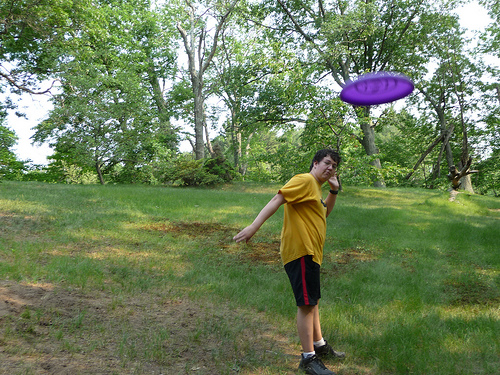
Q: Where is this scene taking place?
A: A park.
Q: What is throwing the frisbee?
A: The man.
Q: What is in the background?
A: The trees.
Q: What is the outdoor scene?
A: It was taken.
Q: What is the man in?
A: Shorts.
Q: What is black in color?
A: Shorts.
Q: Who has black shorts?
A: The man.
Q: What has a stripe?
A: Shorts.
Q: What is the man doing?
A: Playing.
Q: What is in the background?
A: Trees.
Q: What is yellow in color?
A: Shirt.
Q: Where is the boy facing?
A: To the right.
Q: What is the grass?
A: Green.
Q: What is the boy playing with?
A: Frisbee.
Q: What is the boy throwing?
A: A frisbee.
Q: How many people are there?
A: One.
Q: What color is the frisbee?
A: Purple.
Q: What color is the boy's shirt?
A: Yellow.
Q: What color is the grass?
A: Green.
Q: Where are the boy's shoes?
A: On his feet.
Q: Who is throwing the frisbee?
A: The boy.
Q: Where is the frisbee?
A: In the air.